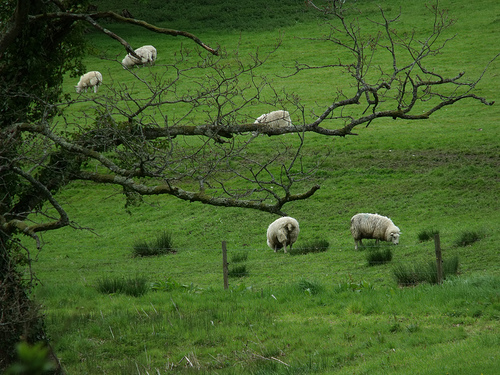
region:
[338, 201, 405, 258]
Sheep eating green grass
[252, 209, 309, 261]
Sheep is eating grass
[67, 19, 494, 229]
Branches of trees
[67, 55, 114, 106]
Sheep eating green grass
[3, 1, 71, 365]
Big tree without leaves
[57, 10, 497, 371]
Prairie has green grass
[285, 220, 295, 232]
Tail of sheep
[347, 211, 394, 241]
Sheep body has wool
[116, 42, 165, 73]
Sheep has head down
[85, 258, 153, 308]
Spots of high grass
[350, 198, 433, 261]
A sheep eating grass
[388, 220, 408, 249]
The head of a sheep eating grass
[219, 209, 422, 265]
Two sheep eating grass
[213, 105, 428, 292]
Three sheep eating grass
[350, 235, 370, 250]
The legs of a sheep eating grass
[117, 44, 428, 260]
Four sheep eating grass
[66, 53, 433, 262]
Five sheep eating grass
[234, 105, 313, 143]
sheep behind a branch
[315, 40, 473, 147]
The branch of a tree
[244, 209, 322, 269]
The back of a sheep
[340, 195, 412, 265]
Sheep is white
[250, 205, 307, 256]
Sheep is eating green grass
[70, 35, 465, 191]
Branch of tree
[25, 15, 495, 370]
Prairie cover with green grass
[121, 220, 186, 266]
Green grass is higher that grass around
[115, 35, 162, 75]
Sheep is eating green grass in the meadow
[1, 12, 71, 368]
Tree on left side of meadow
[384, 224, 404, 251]
Head of sheep is white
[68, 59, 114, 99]
Head of sheep is in green grass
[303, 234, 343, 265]
Shadow of sheep cast on the green grass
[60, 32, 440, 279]
sheep grazing on deep-green grass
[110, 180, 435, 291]
two sheep below the branch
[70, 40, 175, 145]
two sheep above the branch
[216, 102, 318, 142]
one sheep under the branch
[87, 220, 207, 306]
long stems growing in bunches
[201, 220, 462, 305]
wooden poles stuck in the grass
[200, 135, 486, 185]
long patch of soil through the grass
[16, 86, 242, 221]
branches thinning out to twigs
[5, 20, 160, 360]
vine growing up tree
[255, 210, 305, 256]
oval shape of sheep with head down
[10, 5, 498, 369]
Rural vista, during daytime.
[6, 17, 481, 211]
Branches of gnarled tree without leaves.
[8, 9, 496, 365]
Outdoor scene, suggestive of fall.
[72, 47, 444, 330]
Scattered sheep, on green grass.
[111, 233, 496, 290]
Low, wire fencing with wood poles.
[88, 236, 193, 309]
Patches of higher, green grass.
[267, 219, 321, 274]
Tail and rear view of sheep, facing away from photographer.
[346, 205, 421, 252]
Side view of grazing sheep, facing right.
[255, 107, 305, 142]
Obstructed view of sheep, facing left.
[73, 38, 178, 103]
Two, distant sheep, grazing and facing left.